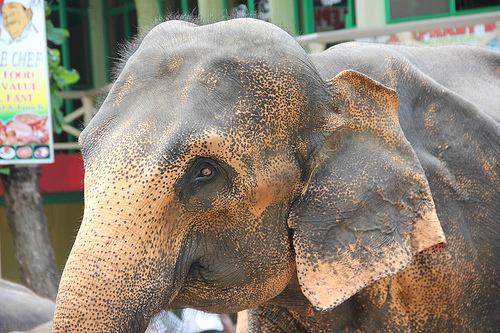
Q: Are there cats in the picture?
A: No, there are no cats.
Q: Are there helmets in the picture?
A: No, there are no helmets.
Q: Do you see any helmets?
A: No, there are no helmets.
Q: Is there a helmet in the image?
A: No, there are no helmets.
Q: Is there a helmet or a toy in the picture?
A: No, there are no helmets or toys.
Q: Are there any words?
A: Yes, there are words.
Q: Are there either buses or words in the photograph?
A: Yes, there are words.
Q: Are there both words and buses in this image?
A: No, there are words but no buses.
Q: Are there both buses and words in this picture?
A: No, there are words but no buses.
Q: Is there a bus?
A: No, there are no buses.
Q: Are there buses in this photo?
A: No, there are no buses.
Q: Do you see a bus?
A: No, there are no buses.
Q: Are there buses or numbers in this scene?
A: No, there are no buses or numbers.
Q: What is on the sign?
A: The words are on the sign.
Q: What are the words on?
A: The words are on the sign.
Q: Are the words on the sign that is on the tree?
A: Yes, the words are on the sign.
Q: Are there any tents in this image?
A: No, there are no tents.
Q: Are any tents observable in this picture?
A: No, there are no tents.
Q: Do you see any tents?
A: No, there are no tents.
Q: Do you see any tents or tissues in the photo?
A: No, there are no tents or tissues.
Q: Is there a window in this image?
A: Yes, there is a window.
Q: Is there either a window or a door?
A: Yes, there is a window.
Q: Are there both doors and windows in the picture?
A: No, there is a window but no doors.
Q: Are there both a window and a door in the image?
A: No, there is a window but no doors.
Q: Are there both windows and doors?
A: No, there is a window but no doors.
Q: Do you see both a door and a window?
A: No, there is a window but no doors.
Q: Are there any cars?
A: No, there are no cars.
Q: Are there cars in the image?
A: No, there are no cars.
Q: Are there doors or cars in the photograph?
A: No, there are no cars or doors.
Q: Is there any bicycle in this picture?
A: No, there are no bicycles.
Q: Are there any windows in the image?
A: Yes, there is a window.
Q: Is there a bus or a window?
A: Yes, there is a window.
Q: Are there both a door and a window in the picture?
A: No, there is a window but no doors.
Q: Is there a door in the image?
A: No, there are no doors.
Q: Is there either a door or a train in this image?
A: No, there are no doors or trains.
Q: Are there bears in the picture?
A: No, there are no bears.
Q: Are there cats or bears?
A: No, there are no bears or cats.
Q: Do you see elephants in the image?
A: Yes, there is an elephant.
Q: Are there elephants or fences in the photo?
A: Yes, there is an elephant.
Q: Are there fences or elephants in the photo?
A: Yes, there is an elephant.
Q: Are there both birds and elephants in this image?
A: No, there is an elephant but no birds.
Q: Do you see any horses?
A: No, there are no horses.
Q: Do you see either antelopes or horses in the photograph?
A: No, there are no horses or antelopes.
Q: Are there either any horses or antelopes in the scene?
A: No, there are no horses or antelopes.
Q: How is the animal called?
A: The animal is an elephant.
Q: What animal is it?
A: The animal is an elephant.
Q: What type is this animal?
A: This is an elephant.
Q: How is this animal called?
A: This is an elephant.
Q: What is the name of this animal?
A: This is an elephant.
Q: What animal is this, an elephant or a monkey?
A: This is an elephant.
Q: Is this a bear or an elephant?
A: This is an elephant.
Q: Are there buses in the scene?
A: No, there are no buses.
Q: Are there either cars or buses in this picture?
A: No, there are no buses or cars.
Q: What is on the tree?
A: The sign is on the tree.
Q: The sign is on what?
A: The sign is on the tree.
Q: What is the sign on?
A: The sign is on the tree.